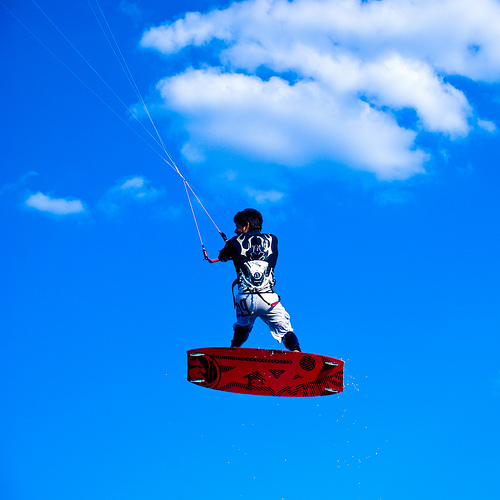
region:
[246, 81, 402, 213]
clouds in clear sky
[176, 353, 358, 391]
windboard in photo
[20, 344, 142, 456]
clear blue sky in photo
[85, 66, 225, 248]
parachute strings in photo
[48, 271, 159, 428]
cloudless sky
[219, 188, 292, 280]
dark skinned man windsurfing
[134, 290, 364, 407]
red windboard in the air in photo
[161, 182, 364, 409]
man windsurfing in photo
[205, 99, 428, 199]
clouds apparent in sky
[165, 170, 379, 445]
dark haired man in the air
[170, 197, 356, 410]
person in the air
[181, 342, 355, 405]
red board under parasail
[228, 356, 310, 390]
black designs on red board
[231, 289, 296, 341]
white pants on person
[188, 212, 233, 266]
cables attached to red rod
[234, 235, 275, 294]
decorative design on shirt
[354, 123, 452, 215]
white clouds in blue sky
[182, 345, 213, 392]
fins underneath parasail board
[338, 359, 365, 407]
water droplets in the air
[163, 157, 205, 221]
cables leading to parasail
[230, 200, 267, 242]
the head of a man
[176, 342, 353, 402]
a surf board under the man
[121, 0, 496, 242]
white clouds in the sky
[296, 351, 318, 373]
a black circle on the surf board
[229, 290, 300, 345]
a white pair of pants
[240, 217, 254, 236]
the ear of a man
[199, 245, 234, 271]
a red handle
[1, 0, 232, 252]
the strings of a parachute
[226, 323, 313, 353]
a pair of black boots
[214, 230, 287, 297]
a black and white shirt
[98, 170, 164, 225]
a cloud in the sky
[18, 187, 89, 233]
a cloud in the sky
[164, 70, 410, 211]
a cloud in the sky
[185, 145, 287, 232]
a cloud in the sky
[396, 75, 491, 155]
a cloud in the sky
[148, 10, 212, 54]
a cloud in the sky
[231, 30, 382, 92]
a cloud in the sky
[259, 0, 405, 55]
a cloud in the sky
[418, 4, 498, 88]
a cloud in the sky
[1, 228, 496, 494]
a blue sky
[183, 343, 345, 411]
the board is red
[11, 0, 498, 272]
the sky has clouds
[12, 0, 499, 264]
the clouds are fluffy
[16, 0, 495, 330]
the clouds are wispy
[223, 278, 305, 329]
the man is wearing suspenders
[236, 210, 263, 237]
the man has black hair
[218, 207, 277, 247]
the man has short hair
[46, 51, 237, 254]
the man is holding a sail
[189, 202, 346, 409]
the man is in the air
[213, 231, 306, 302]
the man is wearing a black and white shirt